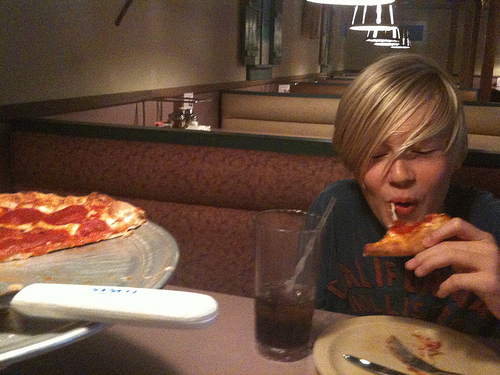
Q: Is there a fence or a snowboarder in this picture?
A: No, there are no fences or snowboarders.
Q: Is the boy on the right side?
A: Yes, the boy is on the right of the image.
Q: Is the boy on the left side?
A: No, the boy is on the right of the image.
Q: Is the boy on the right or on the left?
A: The boy is on the right of the image.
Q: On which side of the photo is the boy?
A: The boy is on the right of the image.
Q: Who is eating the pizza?
A: The boy is eating the pizza.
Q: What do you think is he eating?
A: The boy is eating a pizza.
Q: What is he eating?
A: The boy is eating a pizza.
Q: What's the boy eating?
A: The boy is eating a pizza.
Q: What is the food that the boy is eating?
A: The food is a pizza.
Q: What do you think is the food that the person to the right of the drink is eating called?
A: The food is a pizza.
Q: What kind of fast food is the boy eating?
A: The boy is eating a pizza.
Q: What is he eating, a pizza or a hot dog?
A: The boy is eating a pizza.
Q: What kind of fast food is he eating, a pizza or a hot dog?
A: The boy is eating a pizza.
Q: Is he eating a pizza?
A: Yes, the boy is eating a pizza.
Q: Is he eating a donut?
A: No, the boy is eating a pizza.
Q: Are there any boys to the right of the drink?
A: Yes, there is a boy to the right of the drink.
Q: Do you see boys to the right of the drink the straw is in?
A: Yes, there is a boy to the right of the drink.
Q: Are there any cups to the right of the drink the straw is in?
A: No, there is a boy to the right of the drink.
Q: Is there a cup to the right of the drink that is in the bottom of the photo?
A: No, there is a boy to the right of the drink.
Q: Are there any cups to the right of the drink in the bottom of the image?
A: No, there is a boy to the right of the drink.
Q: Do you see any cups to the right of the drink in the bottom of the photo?
A: No, there is a boy to the right of the drink.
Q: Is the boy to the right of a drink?
A: Yes, the boy is to the right of a drink.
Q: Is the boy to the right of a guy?
A: No, the boy is to the right of a drink.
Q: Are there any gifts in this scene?
A: No, there are no gifts.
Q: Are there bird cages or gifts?
A: No, there are no gifts or bird cages.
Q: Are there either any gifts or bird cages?
A: No, there are no gifts or bird cages.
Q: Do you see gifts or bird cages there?
A: No, there are no gifts or bird cages.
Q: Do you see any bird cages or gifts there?
A: No, there are no gifts or bird cages.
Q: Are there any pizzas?
A: Yes, there is a pizza.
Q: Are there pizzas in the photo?
A: Yes, there is a pizza.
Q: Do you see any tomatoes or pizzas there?
A: Yes, there is a pizza.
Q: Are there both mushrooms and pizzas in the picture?
A: No, there is a pizza but no mushrooms.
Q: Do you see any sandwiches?
A: No, there are no sandwiches.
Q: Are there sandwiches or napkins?
A: No, there are no sandwiches or napkins.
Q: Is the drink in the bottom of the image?
A: Yes, the drink is in the bottom of the image.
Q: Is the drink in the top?
A: No, the drink is in the bottom of the image.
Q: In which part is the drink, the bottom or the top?
A: The drink is in the bottom of the image.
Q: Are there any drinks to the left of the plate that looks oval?
A: Yes, there is a drink to the left of the plate.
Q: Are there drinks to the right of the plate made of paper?
A: No, the drink is to the left of the plate.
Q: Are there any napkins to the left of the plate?
A: No, there is a drink to the left of the plate.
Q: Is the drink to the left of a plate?
A: Yes, the drink is to the left of a plate.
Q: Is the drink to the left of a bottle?
A: No, the drink is to the left of a plate.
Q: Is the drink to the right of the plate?
A: No, the drink is to the left of the plate.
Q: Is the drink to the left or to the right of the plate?
A: The drink is to the left of the plate.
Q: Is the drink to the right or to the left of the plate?
A: The drink is to the left of the plate.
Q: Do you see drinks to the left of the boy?
A: Yes, there is a drink to the left of the boy.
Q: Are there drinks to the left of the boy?
A: Yes, there is a drink to the left of the boy.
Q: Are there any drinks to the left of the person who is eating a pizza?
A: Yes, there is a drink to the left of the boy.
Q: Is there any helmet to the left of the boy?
A: No, there is a drink to the left of the boy.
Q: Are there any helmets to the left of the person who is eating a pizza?
A: No, there is a drink to the left of the boy.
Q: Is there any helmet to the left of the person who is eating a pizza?
A: No, there is a drink to the left of the boy.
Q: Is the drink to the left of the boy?
A: Yes, the drink is to the left of the boy.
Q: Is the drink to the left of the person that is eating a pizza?
A: Yes, the drink is to the left of the boy.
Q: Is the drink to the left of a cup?
A: No, the drink is to the left of the boy.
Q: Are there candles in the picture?
A: No, there are no candles.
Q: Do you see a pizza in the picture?
A: Yes, there is a pizza.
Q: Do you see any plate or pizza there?
A: Yes, there is a pizza.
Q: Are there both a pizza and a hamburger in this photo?
A: No, there is a pizza but no hamburgers.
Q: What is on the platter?
A: The pizza is on the platter.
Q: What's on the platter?
A: The pizza is on the platter.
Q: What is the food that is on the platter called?
A: The food is a pizza.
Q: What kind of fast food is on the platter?
A: The food is a pizza.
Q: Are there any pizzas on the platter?
A: Yes, there is a pizza on the platter.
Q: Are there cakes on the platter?
A: No, there is a pizza on the platter.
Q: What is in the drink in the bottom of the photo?
A: The straw is in the drink.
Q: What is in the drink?
A: The straw is in the drink.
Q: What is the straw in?
A: The straw is in the drink.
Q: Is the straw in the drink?
A: Yes, the straw is in the drink.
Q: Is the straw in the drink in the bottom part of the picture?
A: Yes, the straw is in the drink.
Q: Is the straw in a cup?
A: No, the straw is in the drink.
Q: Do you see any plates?
A: Yes, there is a plate.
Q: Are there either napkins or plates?
A: Yes, there is a plate.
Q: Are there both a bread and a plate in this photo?
A: No, there is a plate but no breads.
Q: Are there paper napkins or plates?
A: Yes, there is a paper plate.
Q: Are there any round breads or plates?
A: Yes, there is a round plate.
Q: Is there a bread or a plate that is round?
A: Yes, the plate is round.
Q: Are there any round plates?
A: Yes, there is a round plate.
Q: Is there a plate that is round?
A: Yes, there is a plate that is round.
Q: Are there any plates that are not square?
A: Yes, there is a round plate.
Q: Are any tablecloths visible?
A: No, there are no tablecloths.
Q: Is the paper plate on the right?
A: Yes, the plate is on the right of the image.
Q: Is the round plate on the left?
A: No, the plate is on the right of the image.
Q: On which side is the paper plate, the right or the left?
A: The plate is on the right of the image.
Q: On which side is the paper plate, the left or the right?
A: The plate is on the right of the image.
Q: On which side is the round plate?
A: The plate is on the right of the image.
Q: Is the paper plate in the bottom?
A: Yes, the plate is in the bottom of the image.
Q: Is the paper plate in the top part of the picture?
A: No, the plate is in the bottom of the image.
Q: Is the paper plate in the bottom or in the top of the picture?
A: The plate is in the bottom of the image.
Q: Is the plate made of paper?
A: Yes, the plate is made of paper.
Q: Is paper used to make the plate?
A: Yes, the plate is made of paper.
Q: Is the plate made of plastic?
A: No, the plate is made of paper.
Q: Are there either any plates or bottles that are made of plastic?
A: No, there is a plate but it is made of paper.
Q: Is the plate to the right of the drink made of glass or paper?
A: The plate is made of paper.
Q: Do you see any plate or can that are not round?
A: No, there is a plate but it is round.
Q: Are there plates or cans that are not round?
A: No, there is a plate but it is round.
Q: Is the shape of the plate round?
A: Yes, the plate is round.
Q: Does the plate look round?
A: Yes, the plate is round.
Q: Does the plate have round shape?
A: Yes, the plate is round.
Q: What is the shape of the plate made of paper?
A: The plate is round.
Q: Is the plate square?
A: No, the plate is round.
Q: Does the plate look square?
A: No, the plate is round.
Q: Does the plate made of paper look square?
A: No, the plate is round.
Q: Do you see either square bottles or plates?
A: No, there is a plate but it is round.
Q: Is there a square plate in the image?
A: No, there is a plate but it is round.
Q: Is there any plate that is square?
A: No, there is a plate but it is round.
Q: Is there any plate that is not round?
A: No, there is a plate but it is round.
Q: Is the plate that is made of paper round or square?
A: The plate is round.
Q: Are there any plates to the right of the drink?
A: Yes, there is a plate to the right of the drink.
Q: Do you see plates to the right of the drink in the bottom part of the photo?
A: Yes, there is a plate to the right of the drink.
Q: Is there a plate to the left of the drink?
A: No, the plate is to the right of the drink.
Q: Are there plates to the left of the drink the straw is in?
A: No, the plate is to the right of the drink.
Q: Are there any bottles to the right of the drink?
A: No, there is a plate to the right of the drink.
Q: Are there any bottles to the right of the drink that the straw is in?
A: No, there is a plate to the right of the drink.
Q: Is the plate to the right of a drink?
A: Yes, the plate is to the right of a drink.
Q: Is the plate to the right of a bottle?
A: No, the plate is to the right of a drink.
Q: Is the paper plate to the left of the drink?
A: No, the plate is to the right of the drink.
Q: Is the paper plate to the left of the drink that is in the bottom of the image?
A: No, the plate is to the right of the drink.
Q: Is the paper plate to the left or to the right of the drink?
A: The plate is to the right of the drink.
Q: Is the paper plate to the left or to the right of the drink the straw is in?
A: The plate is to the right of the drink.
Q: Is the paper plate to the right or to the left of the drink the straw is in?
A: The plate is to the right of the drink.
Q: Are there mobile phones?
A: No, there are no mobile phones.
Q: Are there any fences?
A: No, there are no fences.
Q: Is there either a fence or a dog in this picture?
A: No, there are no fences or dogs.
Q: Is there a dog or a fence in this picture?
A: No, there are no fences or dogs.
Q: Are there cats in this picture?
A: No, there are no cats.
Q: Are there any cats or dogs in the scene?
A: No, there are no cats or dogs.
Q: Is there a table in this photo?
A: Yes, there is a table.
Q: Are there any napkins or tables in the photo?
A: Yes, there is a table.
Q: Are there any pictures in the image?
A: No, there are no pictures.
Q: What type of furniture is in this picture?
A: The furniture is a table.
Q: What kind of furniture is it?
A: The piece of furniture is a table.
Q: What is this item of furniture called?
A: That is a table.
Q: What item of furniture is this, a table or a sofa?
A: That is a table.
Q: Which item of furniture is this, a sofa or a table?
A: That is a table.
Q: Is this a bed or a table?
A: This is a table.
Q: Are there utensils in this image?
A: Yes, there are utensils.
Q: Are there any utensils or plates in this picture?
A: Yes, there are utensils.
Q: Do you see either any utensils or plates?
A: Yes, there are utensils.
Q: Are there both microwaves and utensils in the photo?
A: No, there are utensils but no microwaves.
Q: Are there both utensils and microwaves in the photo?
A: No, there are utensils but no microwaves.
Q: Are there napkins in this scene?
A: No, there are no napkins.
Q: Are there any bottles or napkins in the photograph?
A: No, there are no napkins or bottles.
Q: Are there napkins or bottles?
A: No, there are no napkins or bottles.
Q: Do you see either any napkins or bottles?
A: No, there are no napkins or bottles.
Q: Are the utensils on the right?
A: Yes, the utensils are on the right of the image.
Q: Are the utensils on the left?
A: No, the utensils are on the right of the image.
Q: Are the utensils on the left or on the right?
A: The utensils are on the right of the image.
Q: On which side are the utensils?
A: The utensils are on the right of the image.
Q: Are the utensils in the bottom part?
A: Yes, the utensils are in the bottom of the image.